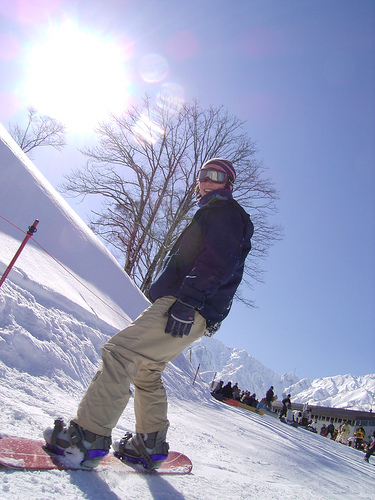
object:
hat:
[202, 157, 237, 179]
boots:
[112, 421, 169, 465]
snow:
[242, 429, 320, 460]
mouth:
[203, 185, 215, 195]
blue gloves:
[164, 298, 196, 338]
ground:
[307, 144, 328, 171]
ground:
[165, 433, 348, 495]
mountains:
[181, 329, 374, 419]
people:
[211, 380, 374, 463]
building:
[268, 399, 375, 443]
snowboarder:
[0, 161, 256, 475]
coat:
[148, 191, 253, 337]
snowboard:
[1, 129, 166, 296]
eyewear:
[195, 168, 227, 183]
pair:
[42, 416, 170, 466]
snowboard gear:
[0, 157, 255, 474]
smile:
[200, 188, 216, 193]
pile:
[1, 129, 95, 371]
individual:
[43, 157, 254, 471]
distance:
[190, 332, 374, 417]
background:
[208, 331, 356, 448]